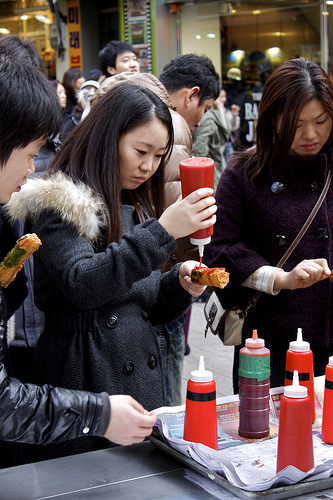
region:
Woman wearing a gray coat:
[30, 72, 207, 413]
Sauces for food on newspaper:
[174, 314, 327, 481]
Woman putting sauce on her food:
[87, 75, 238, 281]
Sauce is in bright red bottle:
[171, 151, 229, 269]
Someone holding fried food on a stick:
[0, 217, 55, 319]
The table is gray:
[24, 414, 250, 497]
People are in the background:
[27, 30, 220, 113]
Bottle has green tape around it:
[229, 321, 276, 445]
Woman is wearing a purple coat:
[220, 43, 332, 360]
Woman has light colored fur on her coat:
[41, 85, 182, 247]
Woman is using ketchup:
[172, 146, 230, 263]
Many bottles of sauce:
[162, 356, 330, 460]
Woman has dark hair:
[84, 53, 176, 189]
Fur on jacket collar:
[35, 165, 106, 265]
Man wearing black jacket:
[4, 386, 97, 447]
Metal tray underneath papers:
[150, 438, 258, 498]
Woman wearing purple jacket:
[234, 148, 315, 265]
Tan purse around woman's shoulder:
[206, 287, 271, 345]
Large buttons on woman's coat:
[99, 300, 167, 384]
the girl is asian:
[52, 75, 182, 239]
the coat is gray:
[47, 209, 190, 405]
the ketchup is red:
[177, 154, 225, 276]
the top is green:
[234, 346, 277, 381]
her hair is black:
[59, 74, 180, 220]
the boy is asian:
[1, 33, 63, 256]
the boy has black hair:
[0, 20, 56, 155]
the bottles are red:
[181, 350, 228, 455]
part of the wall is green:
[117, 4, 133, 52]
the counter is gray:
[46, 460, 132, 487]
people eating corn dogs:
[7, 26, 327, 302]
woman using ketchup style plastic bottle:
[165, 144, 250, 311]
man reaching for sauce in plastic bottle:
[14, 356, 187, 475]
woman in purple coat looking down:
[214, 46, 324, 305]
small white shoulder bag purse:
[195, 281, 257, 346]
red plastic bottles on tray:
[145, 391, 330, 497]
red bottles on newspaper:
[154, 396, 328, 492]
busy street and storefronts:
[13, 11, 306, 70]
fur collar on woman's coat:
[23, 167, 112, 247]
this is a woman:
[43, 94, 180, 370]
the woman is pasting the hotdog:
[44, 93, 220, 355]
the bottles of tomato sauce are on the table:
[179, 327, 321, 464]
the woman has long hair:
[67, 132, 116, 166]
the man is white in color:
[120, 412, 130, 426]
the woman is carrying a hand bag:
[210, 303, 246, 329]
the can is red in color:
[239, 339, 271, 428]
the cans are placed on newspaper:
[222, 463, 265, 474]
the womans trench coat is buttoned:
[109, 309, 157, 379]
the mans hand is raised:
[18, 394, 140, 439]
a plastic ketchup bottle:
[180, 158, 213, 242]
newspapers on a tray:
[154, 406, 328, 470]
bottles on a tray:
[153, 345, 329, 484]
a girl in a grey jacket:
[27, 85, 205, 451]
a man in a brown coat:
[138, 54, 210, 182]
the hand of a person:
[103, 391, 152, 441]